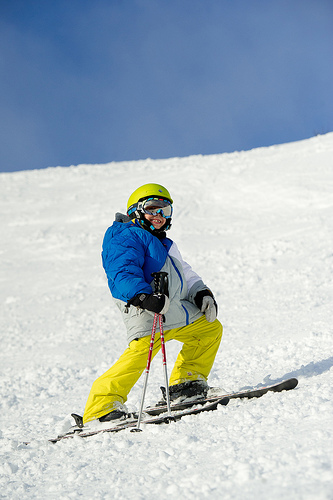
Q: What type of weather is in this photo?
A: It is clear.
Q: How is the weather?
A: It is clear.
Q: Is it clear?
A: Yes, it is clear.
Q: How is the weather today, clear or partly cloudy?
A: It is clear.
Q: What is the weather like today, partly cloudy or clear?
A: It is clear.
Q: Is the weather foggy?
A: No, it is clear.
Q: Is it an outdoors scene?
A: Yes, it is outdoors.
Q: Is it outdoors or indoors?
A: It is outdoors.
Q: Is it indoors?
A: No, it is outdoors.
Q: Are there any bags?
A: No, there are no bags.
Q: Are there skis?
A: Yes, there are skis.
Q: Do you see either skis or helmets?
A: Yes, there are skis.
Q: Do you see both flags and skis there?
A: No, there are skis but no flags.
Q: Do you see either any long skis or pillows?
A: Yes, there are long skis.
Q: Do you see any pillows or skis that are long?
A: Yes, the skis are long.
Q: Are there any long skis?
A: Yes, there are long skis.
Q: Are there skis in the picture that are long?
A: Yes, there are skis that are long.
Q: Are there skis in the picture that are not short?
A: Yes, there are long skis.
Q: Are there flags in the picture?
A: No, there are no flags.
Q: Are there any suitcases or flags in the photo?
A: No, there are no flags or suitcases.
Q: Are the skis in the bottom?
A: Yes, the skis are in the bottom of the image.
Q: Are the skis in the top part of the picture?
A: No, the skis are in the bottom of the image.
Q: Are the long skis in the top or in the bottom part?
A: The skis are in the bottom of the image.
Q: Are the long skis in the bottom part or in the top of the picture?
A: The skis are in the bottom of the image.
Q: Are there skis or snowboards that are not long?
A: No, there are skis but they are long.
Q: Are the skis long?
A: Yes, the skis are long.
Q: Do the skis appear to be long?
A: Yes, the skis are long.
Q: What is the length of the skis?
A: The skis are long.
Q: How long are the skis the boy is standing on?
A: The skis are long.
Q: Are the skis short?
A: No, the skis are long.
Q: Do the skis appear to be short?
A: No, the skis are long.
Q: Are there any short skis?
A: No, there are skis but they are long.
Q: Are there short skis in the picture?
A: No, there are skis but they are long.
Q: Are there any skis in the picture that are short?
A: No, there are skis but they are long.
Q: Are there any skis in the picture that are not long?
A: No, there are skis but they are long.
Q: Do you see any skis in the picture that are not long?
A: No, there are skis but they are long.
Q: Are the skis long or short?
A: The skis are long.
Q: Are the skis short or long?
A: The skis are long.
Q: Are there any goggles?
A: Yes, there are goggles.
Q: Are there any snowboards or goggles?
A: Yes, there are goggles.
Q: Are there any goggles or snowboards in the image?
A: Yes, there are goggles.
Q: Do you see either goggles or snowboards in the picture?
A: Yes, there are goggles.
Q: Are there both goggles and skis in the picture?
A: Yes, there are both goggles and a ski.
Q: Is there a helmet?
A: Yes, there is a helmet.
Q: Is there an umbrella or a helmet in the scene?
A: Yes, there is a helmet.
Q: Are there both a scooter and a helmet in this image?
A: No, there is a helmet but no scooters.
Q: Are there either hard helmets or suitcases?
A: Yes, there is a hard helmet.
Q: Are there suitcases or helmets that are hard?
A: Yes, the helmet is hard.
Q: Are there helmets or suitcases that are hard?
A: Yes, the helmet is hard.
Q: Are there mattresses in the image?
A: No, there are no mattresses.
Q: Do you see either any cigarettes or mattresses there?
A: No, there are no mattresses or cigarettes.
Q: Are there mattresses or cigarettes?
A: No, there are no mattresses or cigarettes.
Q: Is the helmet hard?
A: Yes, the helmet is hard.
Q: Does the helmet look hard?
A: Yes, the helmet is hard.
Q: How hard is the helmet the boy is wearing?
A: The helmet is hard.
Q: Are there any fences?
A: No, there are no fences.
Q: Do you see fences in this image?
A: No, there are no fences.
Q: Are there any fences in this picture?
A: No, there are no fences.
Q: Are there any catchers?
A: No, there are no catchers.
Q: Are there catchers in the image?
A: No, there are no catchers.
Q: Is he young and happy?
A: Yes, the boy is young and happy.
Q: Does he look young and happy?
A: Yes, the boy is young and happy.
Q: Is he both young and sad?
A: No, the boy is young but happy.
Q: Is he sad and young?
A: No, the boy is young but happy.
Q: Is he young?
A: Yes, the boy is young.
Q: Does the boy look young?
A: Yes, the boy is young.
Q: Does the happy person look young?
A: Yes, the boy is young.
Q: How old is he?
A: The boy is young.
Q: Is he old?
A: No, the boy is young.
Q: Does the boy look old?
A: No, the boy is young.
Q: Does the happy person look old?
A: No, the boy is young.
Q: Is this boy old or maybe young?
A: The boy is young.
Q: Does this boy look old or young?
A: The boy is young.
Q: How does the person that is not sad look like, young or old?
A: The boy is young.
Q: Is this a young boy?
A: Yes, this is a young boy.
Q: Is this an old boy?
A: No, this is a young boy.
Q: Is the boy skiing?
A: Yes, the boy is skiing.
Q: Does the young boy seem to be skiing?
A: Yes, the boy is skiing.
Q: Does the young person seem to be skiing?
A: Yes, the boy is skiing.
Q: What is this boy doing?
A: The boy is skiing.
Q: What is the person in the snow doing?
A: The boy is skiing.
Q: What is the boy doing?
A: The boy is skiing.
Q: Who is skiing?
A: The boy is skiing.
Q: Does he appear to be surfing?
A: No, the boy is skiing.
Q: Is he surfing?
A: No, the boy is skiing.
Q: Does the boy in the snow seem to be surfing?
A: No, the boy is skiing.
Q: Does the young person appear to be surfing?
A: No, the boy is skiing.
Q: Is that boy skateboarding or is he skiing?
A: The boy is skiing.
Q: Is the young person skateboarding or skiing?
A: The boy is skiing.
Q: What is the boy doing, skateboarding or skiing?
A: The boy is skiing.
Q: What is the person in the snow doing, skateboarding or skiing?
A: The boy is skiing.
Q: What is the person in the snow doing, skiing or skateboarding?
A: The boy is skiing.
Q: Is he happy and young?
A: Yes, the boy is happy and young.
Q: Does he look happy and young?
A: Yes, the boy is happy and young.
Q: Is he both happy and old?
A: No, the boy is happy but young.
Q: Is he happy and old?
A: No, the boy is happy but young.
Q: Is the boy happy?
A: Yes, the boy is happy.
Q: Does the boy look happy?
A: Yes, the boy is happy.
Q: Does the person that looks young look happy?
A: Yes, the boy is happy.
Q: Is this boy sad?
A: No, the boy is happy.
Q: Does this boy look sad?
A: No, the boy is happy.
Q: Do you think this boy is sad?
A: No, the boy is happy.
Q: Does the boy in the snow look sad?
A: No, the boy is happy.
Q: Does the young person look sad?
A: No, the boy is happy.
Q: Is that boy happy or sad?
A: The boy is happy.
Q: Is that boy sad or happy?
A: The boy is happy.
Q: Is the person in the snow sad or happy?
A: The boy is happy.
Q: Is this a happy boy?
A: Yes, this is a happy boy.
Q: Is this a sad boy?
A: No, this is a happy boy.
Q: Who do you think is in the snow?
A: The boy is in the snow.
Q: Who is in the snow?
A: The boy is in the snow.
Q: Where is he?
A: The boy is in the snow.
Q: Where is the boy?
A: The boy is in the snow.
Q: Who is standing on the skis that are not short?
A: The boy is standing on the skis.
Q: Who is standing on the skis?
A: The boy is standing on the skis.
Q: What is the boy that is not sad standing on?
A: The boy is standing on the skis.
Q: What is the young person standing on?
A: The boy is standing on the skis.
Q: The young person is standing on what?
A: The boy is standing on the skis.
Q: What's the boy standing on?
A: The boy is standing on the skis.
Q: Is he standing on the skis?
A: Yes, the boy is standing on the skis.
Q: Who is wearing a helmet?
A: The boy is wearing a helmet.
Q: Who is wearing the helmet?
A: The boy is wearing a helmet.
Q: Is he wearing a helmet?
A: Yes, the boy is wearing a helmet.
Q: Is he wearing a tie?
A: No, the boy is wearing a helmet.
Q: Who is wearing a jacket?
A: The boy is wearing a jacket.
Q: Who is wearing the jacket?
A: The boy is wearing a jacket.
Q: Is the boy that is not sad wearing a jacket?
A: Yes, the boy is wearing a jacket.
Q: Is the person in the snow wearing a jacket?
A: Yes, the boy is wearing a jacket.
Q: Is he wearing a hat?
A: No, the boy is wearing a jacket.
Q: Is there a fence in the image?
A: No, there are no fences.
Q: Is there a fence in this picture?
A: No, there are no fences.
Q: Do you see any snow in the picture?
A: Yes, there is snow.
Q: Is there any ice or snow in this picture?
A: Yes, there is snow.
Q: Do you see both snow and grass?
A: No, there is snow but no grass.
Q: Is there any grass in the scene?
A: No, there is no grass.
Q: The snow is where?
A: The snow is on the ground.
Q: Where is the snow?
A: The snow is on the ground.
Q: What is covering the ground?
A: The snow is covering the ground.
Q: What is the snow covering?
A: The snow is covering the ground.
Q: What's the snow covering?
A: The snow is covering the ground.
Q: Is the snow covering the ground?
A: Yes, the snow is covering the ground.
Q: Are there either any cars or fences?
A: No, there are no fences or cars.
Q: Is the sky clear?
A: Yes, the sky is clear.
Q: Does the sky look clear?
A: Yes, the sky is clear.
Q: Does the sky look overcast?
A: No, the sky is clear.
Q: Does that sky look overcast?
A: No, the sky is clear.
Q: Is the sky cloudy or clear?
A: The sky is clear.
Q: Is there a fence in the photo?
A: No, there are no fences.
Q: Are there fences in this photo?
A: No, there are no fences.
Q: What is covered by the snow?
A: The ground is covered by the snow.